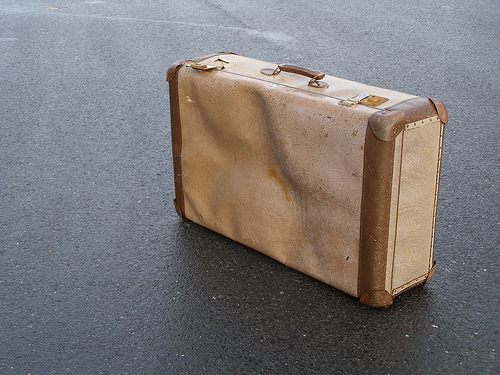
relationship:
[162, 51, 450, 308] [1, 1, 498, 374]
brown suitcase on ground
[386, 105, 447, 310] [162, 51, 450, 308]
rivets on brown suitcase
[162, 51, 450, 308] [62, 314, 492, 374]
brown suitcase on ground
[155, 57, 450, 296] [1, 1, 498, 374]
brown suitcase on ground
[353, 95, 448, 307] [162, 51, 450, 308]
trim on brown suitcase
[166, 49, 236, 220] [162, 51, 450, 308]
trim on brown suitcase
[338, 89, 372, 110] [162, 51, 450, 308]
clasp on brown suitcase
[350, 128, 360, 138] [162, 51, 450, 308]
spots on brown suitcase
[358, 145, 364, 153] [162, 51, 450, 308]
spots on brown suitcase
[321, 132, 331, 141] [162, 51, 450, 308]
spots on brown suitcase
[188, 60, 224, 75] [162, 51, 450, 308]
tear on brown suitcase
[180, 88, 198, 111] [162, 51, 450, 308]
mark on brown suitcase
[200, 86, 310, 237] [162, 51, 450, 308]
dent in brown suitcase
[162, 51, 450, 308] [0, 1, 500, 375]
brown suitcase standing upright ground